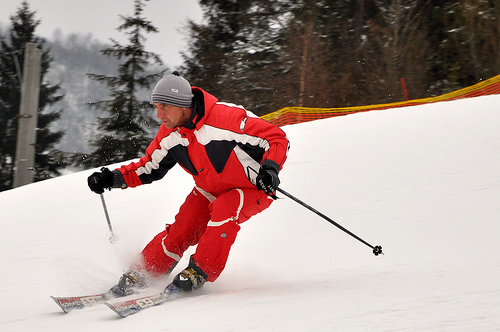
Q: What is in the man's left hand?
A: Ski pole.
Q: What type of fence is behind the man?
A: Orange and yellow fence.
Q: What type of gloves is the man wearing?
A: Black and gray gloves.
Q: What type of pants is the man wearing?
A: Red, white, and black ski pants.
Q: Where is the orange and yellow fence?
A: Behind the man.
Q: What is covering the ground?
A: Snow.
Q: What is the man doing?
A: Skiing in the snow.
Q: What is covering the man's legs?
A: Red and white pants.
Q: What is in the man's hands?
A: Ski poles.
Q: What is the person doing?
A: Skiing.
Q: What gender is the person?
A: Male.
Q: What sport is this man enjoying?
A: Skiing.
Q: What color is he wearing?
A: Red.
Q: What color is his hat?
A: Grey.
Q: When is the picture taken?
A: Daytime.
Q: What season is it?
A: Winter.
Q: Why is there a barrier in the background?
A: No skiing area.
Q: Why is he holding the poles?
A: For control.